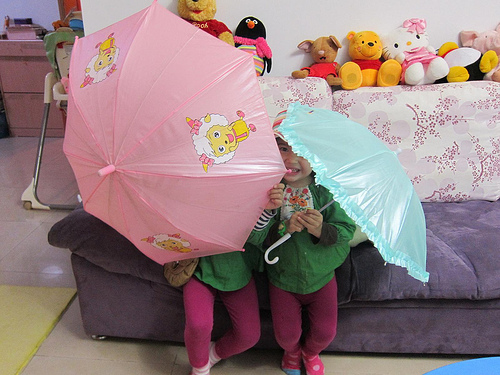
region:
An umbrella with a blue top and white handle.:
[265, 100, 430, 280]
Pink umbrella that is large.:
[61, 0, 286, 265]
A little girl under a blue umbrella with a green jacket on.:
[267, 130, 355, 371]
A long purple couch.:
[48, 79, 498, 359]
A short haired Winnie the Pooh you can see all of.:
[339, 29, 401, 89]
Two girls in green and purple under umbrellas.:
[181, 107, 354, 374]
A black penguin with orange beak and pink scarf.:
[231, 14, 271, 76]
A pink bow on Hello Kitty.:
[402, 17, 426, 38]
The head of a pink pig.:
[454, 22, 499, 55]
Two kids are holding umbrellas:
[61, 0, 434, 373]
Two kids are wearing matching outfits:
[181, 134, 358, 373]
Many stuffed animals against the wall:
[173, 0, 498, 92]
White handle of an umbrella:
[261, 231, 294, 267]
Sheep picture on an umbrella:
[181, 106, 259, 174]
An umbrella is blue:
[262, 98, 433, 286]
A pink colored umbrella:
[60, 1, 294, 267]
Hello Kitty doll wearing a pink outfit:
[380, 15, 451, 88]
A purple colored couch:
[46, 195, 498, 355]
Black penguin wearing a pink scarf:
[232, 12, 274, 79]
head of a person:
[265, 128, 328, 187]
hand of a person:
[303, 205, 325, 245]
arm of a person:
[319, 205, 362, 259]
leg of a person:
[258, 282, 309, 367]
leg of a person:
[306, 305, 353, 357]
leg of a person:
[169, 293, 217, 367]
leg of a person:
[230, 282, 271, 361]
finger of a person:
[302, 207, 327, 228]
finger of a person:
[263, 175, 288, 217]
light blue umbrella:
[273, 104, 437, 279]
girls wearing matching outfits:
[172, 136, 349, 372]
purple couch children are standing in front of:
[48, 113, 493, 355]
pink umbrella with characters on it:
[60, 11, 264, 256]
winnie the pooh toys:
[170, 0, 400, 84]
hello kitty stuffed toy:
[383, 18, 450, 84]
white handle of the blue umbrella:
[260, 233, 291, 267]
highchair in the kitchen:
[27, 33, 89, 219]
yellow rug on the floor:
[2, 283, 80, 369]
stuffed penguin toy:
[438, 36, 498, 86]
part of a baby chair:
[21, 20, 85, 215]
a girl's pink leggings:
[180, 280, 262, 367]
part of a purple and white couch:
[266, 82, 498, 360]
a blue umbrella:
[262, 97, 433, 297]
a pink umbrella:
[62, 1, 279, 270]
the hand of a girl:
[301, 209, 326, 235]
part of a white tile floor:
[32, 328, 135, 373]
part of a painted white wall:
[277, 0, 398, 32]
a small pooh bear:
[341, 30, 398, 92]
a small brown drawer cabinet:
[0, 33, 62, 134]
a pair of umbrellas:
[38, 0, 472, 280]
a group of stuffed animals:
[172, 8, 499, 100]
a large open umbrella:
[256, 101, 435, 287]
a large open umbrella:
[58, 6, 288, 278]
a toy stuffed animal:
[453, 18, 498, 81]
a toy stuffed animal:
[438, 39, 495, 81]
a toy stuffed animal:
[385, 12, 447, 88]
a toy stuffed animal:
[336, 29, 405, 87]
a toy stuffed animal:
[292, 35, 347, 90]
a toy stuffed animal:
[224, 8, 272, 80]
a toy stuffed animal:
[177, 1, 234, 53]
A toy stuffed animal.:
[177, 2, 231, 52]